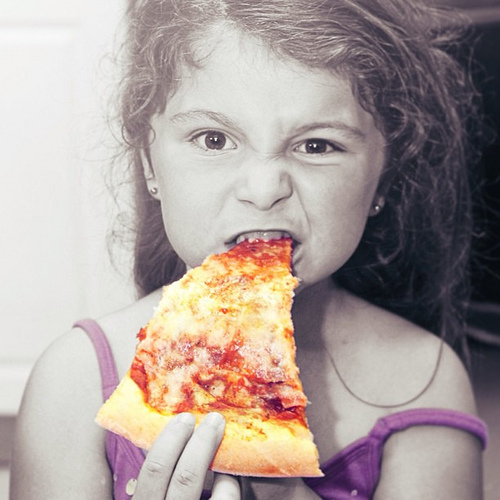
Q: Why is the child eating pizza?
A: She is hungry.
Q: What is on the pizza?
A: Cheese.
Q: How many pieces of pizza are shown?
A: One.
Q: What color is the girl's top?
A: Purple.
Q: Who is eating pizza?
A: The girl.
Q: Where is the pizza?
A: In her hand.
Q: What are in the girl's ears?
A: Earrings.